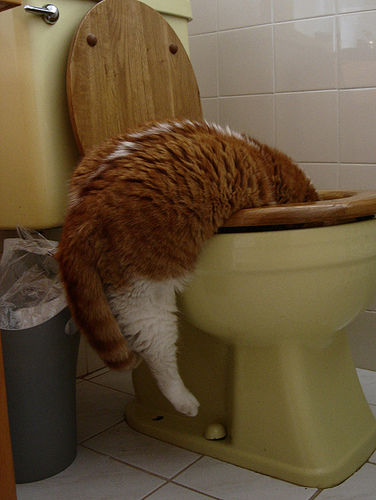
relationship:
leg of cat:
[100, 241, 208, 421] [54, 116, 327, 413]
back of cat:
[106, 118, 273, 169] [54, 116, 327, 413]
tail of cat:
[51, 203, 141, 373] [54, 116, 327, 413]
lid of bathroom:
[63, 1, 207, 154] [0, 0, 376, 499]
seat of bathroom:
[217, 191, 375, 231] [0, 0, 376, 499]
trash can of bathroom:
[1, 235, 96, 483] [3, 2, 374, 499]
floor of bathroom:
[9, 377, 373, 499] [3, 2, 374, 499]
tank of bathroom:
[2, 0, 194, 221] [0, 0, 376, 499]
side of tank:
[0, 4, 62, 233] [2, 0, 194, 221]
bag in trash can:
[5, 238, 71, 329] [1, 235, 96, 483]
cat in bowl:
[54, 116, 327, 413] [179, 219, 375, 356]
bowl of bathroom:
[179, 219, 375, 356] [0, 0, 376, 499]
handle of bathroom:
[16, 1, 67, 31] [0, 0, 376, 499]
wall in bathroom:
[196, 6, 375, 191] [3, 2, 374, 499]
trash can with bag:
[1, 235, 96, 483] [5, 238, 71, 329]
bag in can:
[5, 238, 71, 329] [1, 235, 96, 483]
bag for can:
[5, 238, 71, 329] [1, 235, 96, 483]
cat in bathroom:
[54, 116, 327, 413] [0, 0, 376, 499]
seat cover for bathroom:
[63, 1, 207, 154] [0, 0, 376, 499]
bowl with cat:
[179, 219, 375, 356] [54, 116, 327, 413]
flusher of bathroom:
[16, 1, 67, 31] [0, 0, 376, 499]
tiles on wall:
[266, 6, 372, 171] [196, 6, 375, 191]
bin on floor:
[1, 235, 96, 483] [9, 377, 373, 499]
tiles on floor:
[85, 440, 181, 500] [9, 377, 373, 499]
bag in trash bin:
[5, 238, 71, 329] [1, 235, 96, 483]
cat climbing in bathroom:
[54, 116, 327, 413] [0, 0, 376, 499]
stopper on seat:
[293, 222, 306, 231] [217, 191, 375, 231]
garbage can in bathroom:
[1, 235, 96, 483] [3, 2, 374, 499]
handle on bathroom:
[16, 1, 67, 31] [0, 0, 376, 499]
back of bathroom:
[27, 2, 217, 223] [0, 0, 376, 499]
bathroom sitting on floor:
[0, 0, 376, 499] [9, 377, 373, 499]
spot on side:
[152, 410, 164, 426] [125, 237, 344, 491]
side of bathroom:
[125, 237, 344, 491] [0, 0, 376, 499]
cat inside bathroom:
[54, 116, 327, 413] [0, 0, 376, 499]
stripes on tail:
[75, 306, 123, 361] [51, 203, 141, 373]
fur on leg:
[131, 315, 180, 367] [100, 241, 208, 421]